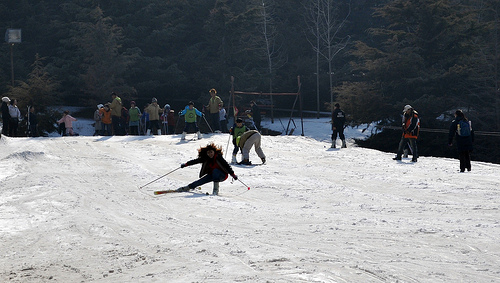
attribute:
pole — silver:
[218, 171, 259, 186]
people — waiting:
[89, 77, 224, 131]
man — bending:
[222, 127, 289, 172]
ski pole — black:
[137, 159, 187, 191]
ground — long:
[423, 137, 448, 177]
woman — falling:
[177, 142, 237, 194]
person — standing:
[176, 141, 237, 196]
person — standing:
[449, 109, 474, 174]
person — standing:
[392, 102, 422, 162]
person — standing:
[230, 131, 266, 165]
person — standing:
[202, 86, 222, 133]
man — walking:
[6, 95, 23, 135]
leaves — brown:
[356, 43, 445, 110]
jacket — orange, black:
[399, 113, 416, 133]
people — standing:
[85, 95, 273, 142]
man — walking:
[330, 104, 349, 149]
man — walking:
[327, 100, 354, 154]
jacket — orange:
[95, 100, 115, 125]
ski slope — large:
[6, 188, 495, 273]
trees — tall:
[39, 5, 234, 94]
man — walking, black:
[388, 102, 432, 194]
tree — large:
[307, 0, 375, 144]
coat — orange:
[399, 101, 421, 148]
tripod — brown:
[226, 79, 312, 109]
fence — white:
[252, 99, 330, 139]